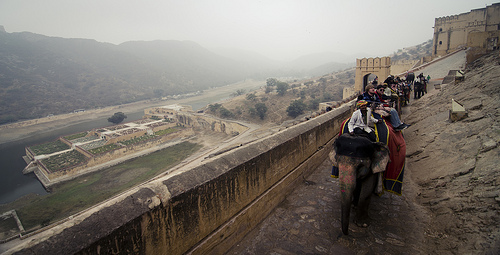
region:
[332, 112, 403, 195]
A colorful blanket draped over the elephant's back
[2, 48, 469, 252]
A centuries old stone wall fortifying a mountain trail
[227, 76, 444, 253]
A mountain trail made of cobbled stones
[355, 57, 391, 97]
A stone arch leading to a castle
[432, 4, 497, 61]
An imposing castle on the side of a mountain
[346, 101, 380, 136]
A man riding an elephant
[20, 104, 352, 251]
Black stains cover the stone wall from centuries of lit torches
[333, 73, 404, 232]
people riding elephants in line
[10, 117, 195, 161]
the city down below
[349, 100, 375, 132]
man on an elephant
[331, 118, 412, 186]
drape over elephant's body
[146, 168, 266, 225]
wall on elevated land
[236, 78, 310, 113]
trees and shrubs on land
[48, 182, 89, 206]
grass area down below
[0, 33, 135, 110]
elevated terrain in the distance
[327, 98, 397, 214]
the man is on an elephant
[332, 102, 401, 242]
the man is riding an elephant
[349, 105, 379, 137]
the man is wearing a white jacket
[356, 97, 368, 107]
the man is wearing a hat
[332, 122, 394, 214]
the elephant is brown in color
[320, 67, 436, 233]
a group of elephants is on the walk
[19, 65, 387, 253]
the wall is made of concrete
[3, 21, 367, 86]
a mountain range is in the distance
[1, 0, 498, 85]
haze is in the atmosphere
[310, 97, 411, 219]
elephant with people on it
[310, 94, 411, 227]
elephant with people on it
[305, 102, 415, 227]
elephant with people on it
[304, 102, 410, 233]
elephant with people on it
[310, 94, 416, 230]
elephant with people on it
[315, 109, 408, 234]
elephant with people on it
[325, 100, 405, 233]
elephant with people on it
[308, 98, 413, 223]
elephant with people on it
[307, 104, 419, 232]
elephant with people on it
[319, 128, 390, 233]
An elephant is walking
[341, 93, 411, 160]
People are riding on an elephant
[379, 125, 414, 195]
Red clothe over an elephant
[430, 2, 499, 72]
Beige building in the background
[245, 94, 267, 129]
Green tree at the distance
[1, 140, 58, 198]
Body of water at the distance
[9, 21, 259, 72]
Mountains at the distance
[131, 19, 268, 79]
Fog covering up the mountains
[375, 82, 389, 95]
Man is wearing sunglasses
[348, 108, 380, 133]
Man wearing a white jacket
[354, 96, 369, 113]
Head of a man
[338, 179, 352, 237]
Trunk of an elephant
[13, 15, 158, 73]
Mountains in the distance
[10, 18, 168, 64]
Mountains in the distance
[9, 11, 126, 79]
Mountains in the distance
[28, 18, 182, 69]
Mountains in the distance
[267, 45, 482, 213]
animals on the ground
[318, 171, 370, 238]
trunk of the elephant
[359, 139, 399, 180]
ear of the elephant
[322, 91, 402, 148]
person on the elephant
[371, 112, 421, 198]
object on the elephant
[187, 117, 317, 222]
fence next to the elephant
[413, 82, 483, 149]
object on the ground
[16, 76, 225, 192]
ground in the distance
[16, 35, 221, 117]
hills in the distance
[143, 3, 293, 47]
sky above the land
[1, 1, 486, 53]
A grey cloudy sky.